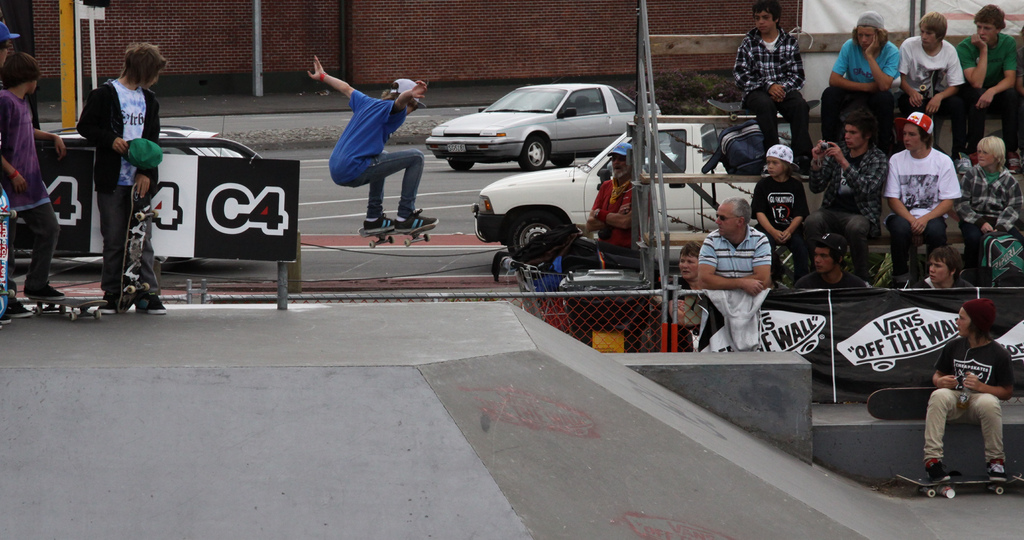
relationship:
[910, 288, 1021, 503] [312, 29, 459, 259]
person watching skateboarder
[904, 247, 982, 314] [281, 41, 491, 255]
person watching skateboarder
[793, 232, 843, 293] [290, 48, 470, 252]
person watching skateboarder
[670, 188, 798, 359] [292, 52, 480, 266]
person watching skateboarder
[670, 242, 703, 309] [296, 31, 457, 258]
person watching skateboarder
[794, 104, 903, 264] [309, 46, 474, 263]
person watching skateboarder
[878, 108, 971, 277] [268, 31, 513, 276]
person watching skateboarder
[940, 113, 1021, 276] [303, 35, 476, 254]
person watching skateboarder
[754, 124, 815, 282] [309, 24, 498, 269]
person watching skateboarder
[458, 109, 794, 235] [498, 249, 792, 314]
truck parked on side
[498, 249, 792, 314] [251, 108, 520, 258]
side of road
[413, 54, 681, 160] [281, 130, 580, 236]
car in road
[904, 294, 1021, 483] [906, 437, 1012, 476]
skater has h feet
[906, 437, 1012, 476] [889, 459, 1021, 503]
feet on skateboard